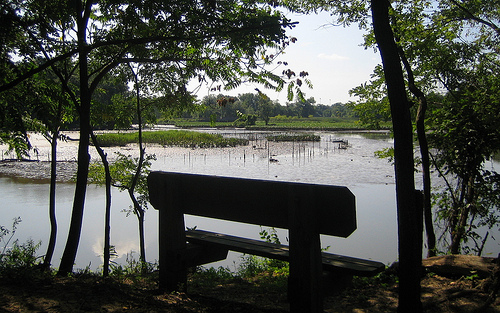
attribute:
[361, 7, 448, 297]
tree trunk — tall, skinny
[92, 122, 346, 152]
islands — green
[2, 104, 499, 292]
lake — calm, shallow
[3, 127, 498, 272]
water — gray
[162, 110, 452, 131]
grass — green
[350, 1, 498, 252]
tree — small, green, lakeside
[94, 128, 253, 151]
island — small, grassy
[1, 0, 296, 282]
trees — thin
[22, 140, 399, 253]
water — brown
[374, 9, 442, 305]
trees — black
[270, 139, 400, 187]
water — reflective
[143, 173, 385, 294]
bench — black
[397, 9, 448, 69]
leaves — green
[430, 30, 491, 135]
leaves — green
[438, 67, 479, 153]
leaves — green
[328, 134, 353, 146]
log — dead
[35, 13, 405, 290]
park — nature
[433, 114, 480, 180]
leaves — green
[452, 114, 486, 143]
leaves — green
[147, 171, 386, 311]
bench — wooden